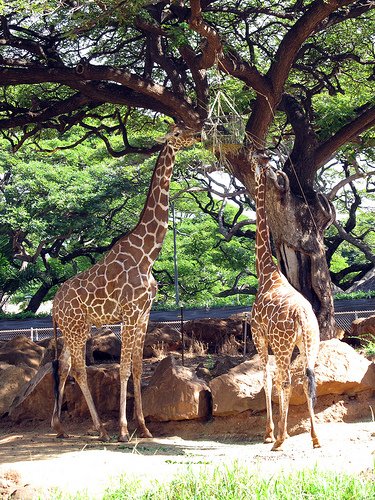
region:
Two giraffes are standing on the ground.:
[43, 118, 328, 455]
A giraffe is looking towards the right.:
[39, 111, 186, 442]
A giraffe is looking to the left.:
[219, 115, 332, 454]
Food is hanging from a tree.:
[151, 69, 274, 183]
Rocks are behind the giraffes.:
[0, 310, 370, 425]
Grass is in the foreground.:
[19, 458, 369, 495]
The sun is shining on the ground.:
[0, 416, 371, 494]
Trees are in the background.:
[0, 102, 371, 307]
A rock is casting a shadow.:
[188, 379, 218, 424]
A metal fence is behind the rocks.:
[0, 303, 373, 348]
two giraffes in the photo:
[50, 124, 328, 454]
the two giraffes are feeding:
[51, 126, 340, 459]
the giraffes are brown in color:
[51, 118, 321, 447]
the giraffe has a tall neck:
[105, 111, 192, 258]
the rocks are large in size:
[145, 354, 260, 412]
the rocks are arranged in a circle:
[156, 313, 251, 351]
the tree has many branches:
[28, 0, 372, 105]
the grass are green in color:
[47, 468, 372, 498]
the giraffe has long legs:
[48, 325, 142, 434]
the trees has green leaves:
[172, 208, 236, 270]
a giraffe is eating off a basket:
[41, 121, 203, 451]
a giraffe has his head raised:
[25, 120, 204, 441]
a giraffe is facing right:
[50, 126, 203, 449]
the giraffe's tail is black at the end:
[49, 360, 65, 415]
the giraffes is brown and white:
[37, 122, 199, 452]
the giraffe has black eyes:
[173, 130, 182, 138]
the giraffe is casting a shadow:
[2, 427, 209, 472]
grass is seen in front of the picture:
[43, 466, 370, 496]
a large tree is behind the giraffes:
[2, 3, 373, 335]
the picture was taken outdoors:
[1, 0, 373, 498]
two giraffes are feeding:
[0, 110, 347, 450]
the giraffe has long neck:
[117, 116, 190, 247]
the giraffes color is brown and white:
[9, 118, 337, 453]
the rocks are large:
[155, 355, 250, 419]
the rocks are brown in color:
[150, 354, 260, 411]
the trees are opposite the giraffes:
[182, 275, 255, 297]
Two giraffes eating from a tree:
[41, 117, 336, 456]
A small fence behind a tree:
[331, 303, 373, 341]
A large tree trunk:
[257, 129, 340, 331]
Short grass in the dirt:
[98, 456, 374, 497]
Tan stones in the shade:
[145, 315, 260, 423]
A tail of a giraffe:
[50, 298, 67, 428]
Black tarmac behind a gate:
[145, 299, 257, 324]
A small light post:
[240, 310, 252, 360]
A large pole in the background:
[168, 197, 179, 310]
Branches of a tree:
[184, 160, 257, 254]